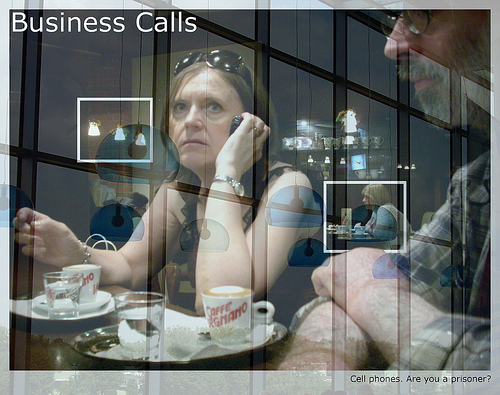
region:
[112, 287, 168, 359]
a clear glass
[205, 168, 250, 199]
a woman's watch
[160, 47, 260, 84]
dark black sunglasses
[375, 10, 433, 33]
a man's eyeglasses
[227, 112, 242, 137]
part of a black cellphone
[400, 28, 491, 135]
the beard of a man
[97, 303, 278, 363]
a white piece of a paper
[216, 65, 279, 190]
part of a woman's brown hair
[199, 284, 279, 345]
a small tea cup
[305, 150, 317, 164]
a wall lamp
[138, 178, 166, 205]
part of a glass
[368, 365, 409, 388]
part of a graphic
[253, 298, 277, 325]
part of a handle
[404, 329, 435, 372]
part of a sleeve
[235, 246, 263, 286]
edge of an arm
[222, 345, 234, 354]
part of a plate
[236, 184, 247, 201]
part of a watch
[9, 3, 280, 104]
business calls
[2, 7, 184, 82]
business calls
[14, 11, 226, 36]
business calls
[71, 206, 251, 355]
a glass of water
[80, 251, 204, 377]
a glass of water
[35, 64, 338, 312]
A woman talking on her phone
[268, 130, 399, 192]
A ledge holding cups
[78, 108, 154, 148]
Three white lights hanging together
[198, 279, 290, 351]
A white cup with red letters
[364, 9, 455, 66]
Glasses worn by man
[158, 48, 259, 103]
Glasses on top of woman's head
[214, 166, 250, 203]
Silver watch on woman's wrist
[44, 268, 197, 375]
Two glasses of water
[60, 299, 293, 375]
Silver plate with water and coffee cup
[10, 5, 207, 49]
Business Calls in white letters